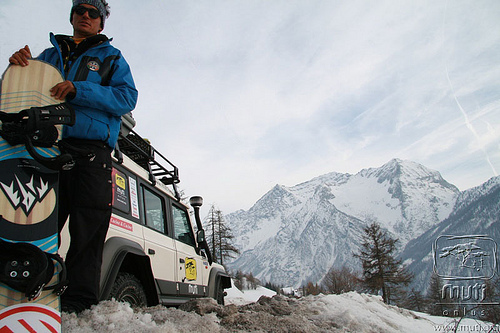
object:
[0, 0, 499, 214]
sky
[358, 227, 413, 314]
tree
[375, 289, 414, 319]
snow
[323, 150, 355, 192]
ground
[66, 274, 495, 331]
snow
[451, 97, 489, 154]
streaks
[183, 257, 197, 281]
picture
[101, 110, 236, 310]
car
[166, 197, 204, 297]
door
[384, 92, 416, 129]
ground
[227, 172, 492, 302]
snow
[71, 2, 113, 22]
snow hat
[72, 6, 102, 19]
sunglasses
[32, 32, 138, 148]
blue coat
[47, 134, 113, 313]
pants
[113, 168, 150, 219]
stickers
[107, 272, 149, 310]
wheel well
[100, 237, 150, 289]
plastic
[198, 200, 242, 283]
trees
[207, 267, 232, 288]
bumper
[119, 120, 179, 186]
rooftrack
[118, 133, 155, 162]
luggage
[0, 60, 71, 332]
snowboard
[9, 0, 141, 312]
man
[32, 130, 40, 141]
gear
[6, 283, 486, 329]
ground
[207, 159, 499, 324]
mountain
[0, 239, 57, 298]
foot strap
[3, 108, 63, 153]
foot strap